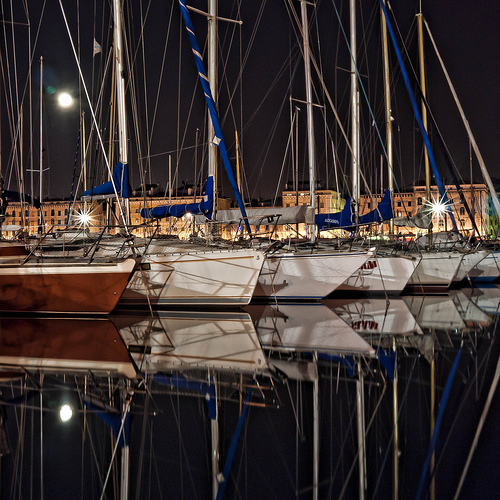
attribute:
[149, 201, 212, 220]
cloth — blue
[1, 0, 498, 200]
sky — black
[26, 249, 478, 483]
water — still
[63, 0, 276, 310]
boat — white